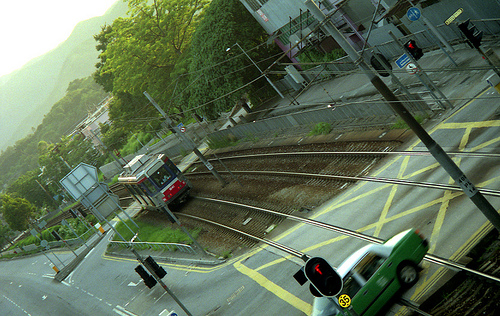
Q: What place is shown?
A: It is a walkway.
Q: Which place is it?
A: It is a walkway.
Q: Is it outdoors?
A: Yes, it is outdoors.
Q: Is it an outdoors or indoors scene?
A: It is outdoors.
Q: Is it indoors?
A: No, it is outdoors.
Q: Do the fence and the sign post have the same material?
A: Yes, both the fence and the sign post are made of metal.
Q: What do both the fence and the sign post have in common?
A: The material, both the fence and the sign post are metallic.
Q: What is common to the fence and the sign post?
A: The material, both the fence and the sign post are metallic.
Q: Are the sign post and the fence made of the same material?
A: Yes, both the sign post and the fence are made of metal.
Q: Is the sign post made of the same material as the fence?
A: Yes, both the sign post and the fence are made of metal.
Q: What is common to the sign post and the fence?
A: The material, both the sign post and the fence are metallic.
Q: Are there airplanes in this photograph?
A: No, there are no airplanes.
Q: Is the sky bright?
A: Yes, the sky is bright.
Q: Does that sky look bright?
A: Yes, the sky is bright.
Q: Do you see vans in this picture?
A: No, there are no vans.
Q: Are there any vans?
A: No, there are no vans.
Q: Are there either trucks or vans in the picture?
A: No, there are no vans or trucks.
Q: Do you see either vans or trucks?
A: No, there are no vans or trucks.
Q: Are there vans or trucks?
A: No, there are no vans or trucks.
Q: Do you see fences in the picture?
A: Yes, there is a fence.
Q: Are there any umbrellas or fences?
A: Yes, there is a fence.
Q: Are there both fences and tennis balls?
A: No, there is a fence but no tennis balls.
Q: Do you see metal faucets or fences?
A: Yes, there is a metal fence.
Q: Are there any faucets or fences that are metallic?
A: Yes, the fence is metallic.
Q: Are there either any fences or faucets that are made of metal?
A: Yes, the fence is made of metal.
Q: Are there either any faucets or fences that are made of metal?
A: Yes, the fence is made of metal.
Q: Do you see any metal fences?
A: Yes, there is a metal fence.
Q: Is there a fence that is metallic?
A: Yes, there is a fence that is metallic.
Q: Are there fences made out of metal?
A: Yes, there is a fence that is made of metal.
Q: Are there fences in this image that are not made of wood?
A: Yes, there is a fence that is made of metal.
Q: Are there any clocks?
A: No, there are no clocks.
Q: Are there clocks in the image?
A: No, there are no clocks.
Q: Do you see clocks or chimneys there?
A: No, there are no clocks or chimneys.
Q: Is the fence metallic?
A: Yes, the fence is metallic.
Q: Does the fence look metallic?
A: Yes, the fence is metallic.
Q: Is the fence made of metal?
A: Yes, the fence is made of metal.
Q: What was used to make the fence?
A: The fence is made of metal.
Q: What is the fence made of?
A: The fence is made of metal.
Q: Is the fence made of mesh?
A: No, the fence is made of metal.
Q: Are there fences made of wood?
A: No, there is a fence but it is made of metal.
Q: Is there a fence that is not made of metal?
A: No, there is a fence but it is made of metal.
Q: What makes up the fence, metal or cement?
A: The fence is made of metal.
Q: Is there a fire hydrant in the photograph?
A: No, there are no fire hydrants.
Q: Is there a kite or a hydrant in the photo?
A: No, there are no fire hydrants or kites.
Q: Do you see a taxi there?
A: Yes, there is a taxi.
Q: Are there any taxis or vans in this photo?
A: Yes, there is a taxi.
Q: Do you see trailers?
A: No, there are no trailers.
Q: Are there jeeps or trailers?
A: No, there are no trailers or jeeps.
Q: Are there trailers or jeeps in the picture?
A: No, there are no trailers or jeeps.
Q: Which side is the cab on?
A: The cab is on the right of the image.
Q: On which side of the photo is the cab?
A: The cab is on the right of the image.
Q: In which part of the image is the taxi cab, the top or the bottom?
A: The taxi cab is in the bottom of the image.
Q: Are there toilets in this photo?
A: No, there are no toilets.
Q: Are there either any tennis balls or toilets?
A: No, there are no toilets or tennis balls.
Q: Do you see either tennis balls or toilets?
A: No, there are no toilets or tennis balls.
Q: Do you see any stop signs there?
A: Yes, there is a stop sign.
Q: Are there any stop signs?
A: Yes, there is a stop sign.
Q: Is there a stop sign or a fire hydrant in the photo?
A: Yes, there is a stop sign.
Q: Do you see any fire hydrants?
A: No, there are no fire hydrants.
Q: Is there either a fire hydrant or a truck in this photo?
A: No, there are no fire hydrants or trucks.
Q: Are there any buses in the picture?
A: No, there are no buses.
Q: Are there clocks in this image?
A: No, there are no clocks.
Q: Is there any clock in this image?
A: No, there are no clocks.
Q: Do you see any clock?
A: No, there are no clocks.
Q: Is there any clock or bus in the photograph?
A: No, there are no clocks or buses.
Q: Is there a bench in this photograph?
A: No, there are no benches.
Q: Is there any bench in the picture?
A: No, there are no benches.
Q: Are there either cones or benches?
A: No, there are no benches or cones.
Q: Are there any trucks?
A: No, there are no trucks.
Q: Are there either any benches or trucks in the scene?
A: No, there are no trucks or benches.